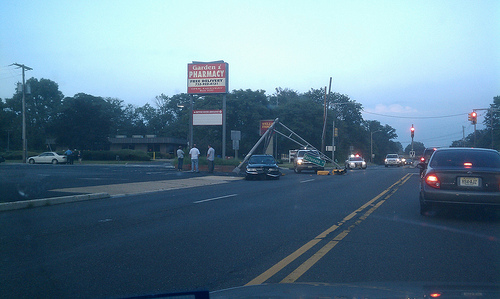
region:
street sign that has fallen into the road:
[233, 118, 345, 174]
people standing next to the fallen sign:
[177, 146, 216, 171]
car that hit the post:
[246, 155, 280, 177]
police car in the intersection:
[345, 150, 366, 170]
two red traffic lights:
[408, 115, 478, 137]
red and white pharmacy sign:
[187, 57, 224, 163]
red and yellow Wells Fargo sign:
[261, 118, 276, 135]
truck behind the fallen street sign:
[295, 146, 320, 172]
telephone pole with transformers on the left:
[9, 61, 34, 160]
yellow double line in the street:
[240, 173, 405, 283]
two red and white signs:
[182, 52, 235, 159]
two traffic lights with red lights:
[390, 110, 478, 145]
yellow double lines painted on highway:
[254, 159, 431, 284]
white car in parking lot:
[25, 148, 68, 166]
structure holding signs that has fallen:
[225, 107, 351, 179]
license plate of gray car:
[457, 175, 482, 186]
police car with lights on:
[342, 148, 374, 173]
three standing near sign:
[172, 141, 220, 169]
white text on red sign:
[185, 60, 267, 70]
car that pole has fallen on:
[238, 150, 278, 176]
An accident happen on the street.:
[169, 107, 354, 200]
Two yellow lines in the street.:
[278, 212, 380, 276]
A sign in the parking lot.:
[169, 58, 238, 164]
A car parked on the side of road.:
[16, 140, 79, 178]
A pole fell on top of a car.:
[246, 97, 335, 179]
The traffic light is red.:
[321, 87, 496, 152]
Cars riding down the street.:
[396, 132, 496, 212]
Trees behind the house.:
[33, 78, 212, 162]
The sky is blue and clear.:
[122, 27, 465, 119]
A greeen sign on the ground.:
[296, 129, 341, 176]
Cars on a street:
[367, 99, 494, 244]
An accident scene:
[238, 95, 367, 196]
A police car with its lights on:
[342, 149, 369, 169]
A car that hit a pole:
[239, 149, 285, 181]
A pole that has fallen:
[220, 112, 346, 177]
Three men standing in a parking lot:
[170, 138, 221, 175]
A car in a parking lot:
[27, 145, 73, 168]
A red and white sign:
[178, 54, 237, 106]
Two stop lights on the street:
[401, 105, 484, 137]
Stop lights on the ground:
[314, 142, 354, 182]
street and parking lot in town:
[18, 35, 493, 268]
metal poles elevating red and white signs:
[183, 50, 224, 166]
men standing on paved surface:
[171, 137, 216, 174]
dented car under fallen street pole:
[230, 106, 341, 178]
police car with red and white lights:
[340, 150, 366, 172]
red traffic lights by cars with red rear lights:
[405, 105, 490, 210]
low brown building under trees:
[100, 105, 185, 160]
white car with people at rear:
[20, 145, 75, 165]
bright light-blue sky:
[20, 15, 478, 132]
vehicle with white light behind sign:
[287, 141, 327, 176]